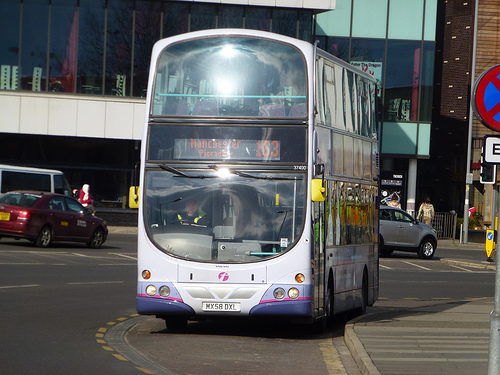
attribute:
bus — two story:
[134, 25, 384, 329]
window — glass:
[47, 18, 135, 90]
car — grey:
[376, 204, 439, 258]